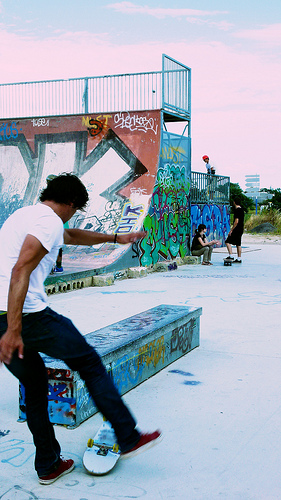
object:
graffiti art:
[133, 164, 192, 266]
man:
[0, 173, 161, 486]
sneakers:
[35, 445, 77, 484]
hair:
[38, 172, 89, 209]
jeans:
[0, 306, 139, 470]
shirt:
[0, 203, 65, 316]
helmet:
[202, 155, 209, 160]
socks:
[237, 257, 242, 261]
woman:
[191, 224, 222, 266]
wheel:
[88, 437, 94, 447]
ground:
[0, 225, 281, 497]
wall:
[0, 106, 193, 288]